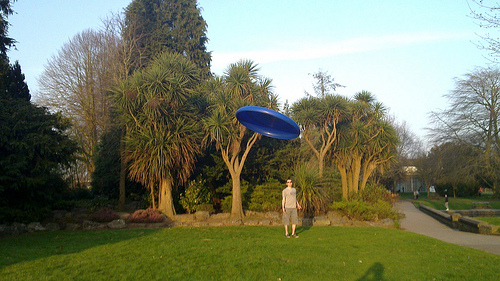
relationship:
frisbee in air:
[236, 106, 300, 140] [1, 1, 500, 280]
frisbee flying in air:
[236, 106, 300, 140] [1, 1, 500, 280]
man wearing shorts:
[281, 178, 302, 239] [283, 207, 298, 225]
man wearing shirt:
[281, 178, 302, 239] [281, 187, 297, 208]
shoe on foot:
[284, 232, 291, 238] [284, 233, 290, 239]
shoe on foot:
[291, 233, 299, 237] [291, 233, 299, 238]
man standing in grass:
[281, 178, 302, 239] [1, 192, 499, 280]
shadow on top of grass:
[358, 261, 384, 280] [1, 192, 499, 280]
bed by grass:
[40, 212, 84, 230] [1, 192, 499, 280]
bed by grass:
[87, 207, 121, 222] [1, 192, 499, 280]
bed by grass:
[128, 207, 164, 223] [1, 192, 499, 280]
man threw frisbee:
[281, 178, 302, 239] [236, 106, 300, 140]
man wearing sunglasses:
[281, 178, 302, 239] [286, 181, 292, 184]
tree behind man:
[109, 51, 209, 215] [281, 178, 302, 239]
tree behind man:
[200, 59, 279, 218] [281, 178, 302, 239]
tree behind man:
[290, 94, 354, 182] [281, 178, 302, 239]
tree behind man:
[336, 90, 399, 200] [281, 178, 302, 239]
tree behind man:
[290, 161, 330, 215] [281, 178, 302, 239]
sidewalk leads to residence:
[391, 198, 499, 257] [390, 159, 448, 193]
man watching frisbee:
[281, 178, 302, 239] [236, 106, 300, 140]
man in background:
[281, 178, 302, 239] [0, 1, 499, 239]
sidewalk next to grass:
[391, 198, 499, 257] [1, 192, 499, 280]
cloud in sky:
[210, 36, 465, 70] [0, 0, 499, 175]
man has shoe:
[281, 178, 302, 239] [284, 232, 291, 238]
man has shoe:
[281, 178, 302, 239] [291, 233, 299, 237]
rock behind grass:
[26, 220, 47, 231] [1, 192, 499, 280]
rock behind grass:
[107, 218, 127, 229] [1, 192, 499, 280]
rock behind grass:
[195, 209, 210, 219] [1, 192, 499, 280]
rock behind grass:
[210, 212, 231, 219] [1, 192, 499, 280]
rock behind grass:
[314, 215, 332, 226] [1, 192, 499, 280]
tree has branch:
[290, 94, 354, 182] [302, 128, 320, 160]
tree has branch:
[290, 94, 354, 182] [319, 126, 326, 154]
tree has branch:
[290, 94, 354, 182] [324, 122, 331, 143]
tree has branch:
[200, 59, 279, 218] [239, 132, 259, 173]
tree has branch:
[200, 59, 279, 218] [221, 138, 238, 173]